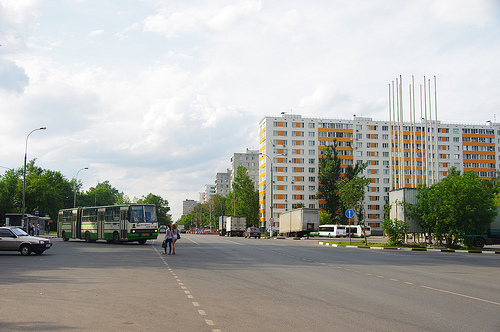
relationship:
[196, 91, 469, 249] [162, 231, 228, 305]
buildings along paved road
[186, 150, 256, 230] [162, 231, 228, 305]
trees along paved road